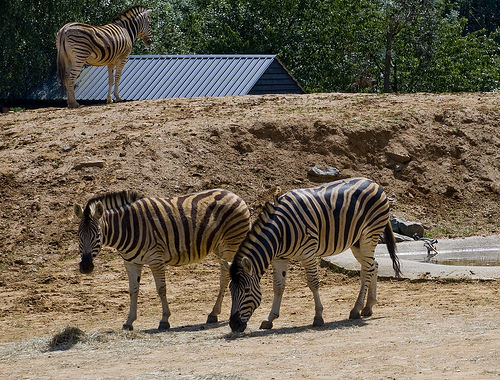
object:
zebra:
[73, 188, 251, 329]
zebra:
[224, 176, 401, 334]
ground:
[0, 90, 497, 380]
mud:
[0, 91, 498, 336]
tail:
[379, 215, 404, 281]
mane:
[113, 0, 146, 21]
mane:
[79, 189, 140, 214]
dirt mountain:
[1, 90, 500, 380]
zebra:
[56, 2, 159, 104]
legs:
[122, 256, 181, 325]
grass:
[1, 325, 152, 356]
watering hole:
[351, 236, 499, 267]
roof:
[27, 52, 307, 102]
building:
[23, 54, 309, 109]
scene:
[3, 4, 498, 376]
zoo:
[2, 2, 498, 379]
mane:
[229, 199, 274, 271]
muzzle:
[76, 251, 96, 275]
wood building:
[41, 55, 302, 103]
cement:
[326, 240, 499, 278]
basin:
[383, 238, 498, 285]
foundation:
[417, 281, 498, 313]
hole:
[413, 253, 500, 268]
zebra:
[48, 4, 153, 109]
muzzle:
[229, 304, 256, 349]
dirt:
[0, 89, 500, 380]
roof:
[31, 53, 304, 105]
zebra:
[71, 187, 255, 334]